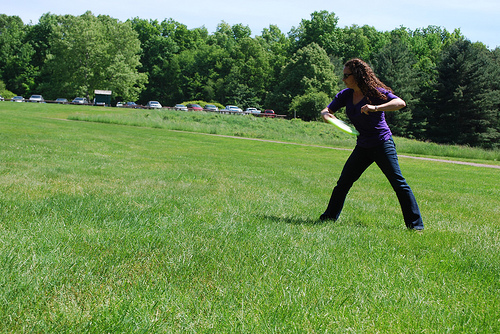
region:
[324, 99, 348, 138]
yellow Frisbee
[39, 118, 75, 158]
short green and yellow grass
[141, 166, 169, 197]
short green and yellow grass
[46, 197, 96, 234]
short green and yellow grass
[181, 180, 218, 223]
short green and yellow grass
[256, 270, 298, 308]
short green and yellow grass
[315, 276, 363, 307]
short green and yellow grass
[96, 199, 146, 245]
short green and yellow grass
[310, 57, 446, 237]
the woman has glasses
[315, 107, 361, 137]
the frisbee is white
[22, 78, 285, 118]
the cars are parked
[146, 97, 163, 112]
the car is white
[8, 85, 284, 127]
the cars are twelve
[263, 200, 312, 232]
shadow is on the ground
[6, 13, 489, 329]
the scene is outdoors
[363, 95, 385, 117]
watch is on the wrist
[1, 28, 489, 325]
the game being played is frisbee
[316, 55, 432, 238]
A woman playing frisbee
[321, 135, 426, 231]
A pair of blue jeans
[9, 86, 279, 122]
Cars parked in a parking lot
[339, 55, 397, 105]
Woman has long brown hair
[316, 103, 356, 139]
Frisbee in a hand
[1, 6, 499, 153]
Many green trees in the background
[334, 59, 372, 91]
Woman is wearing sunglasses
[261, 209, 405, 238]
Shadows on the grass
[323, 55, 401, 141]
A purple colored shirt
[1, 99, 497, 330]
A large grassy field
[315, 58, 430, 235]
Woman preparing to throw frisbee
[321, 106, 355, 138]
White plastic frisbee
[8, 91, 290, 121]
Line of parked cars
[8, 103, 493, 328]
Gras covered park field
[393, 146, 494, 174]
Park dirt trail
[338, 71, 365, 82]
Sunglases on woman's face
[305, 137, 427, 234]
Blue denim pants on woman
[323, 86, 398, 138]
Purple shirt on woman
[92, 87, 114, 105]
Park rest room facilities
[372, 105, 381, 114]
Watch on woman's wrist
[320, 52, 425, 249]
girl standing in a grassy field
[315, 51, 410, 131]
girl playing frisbee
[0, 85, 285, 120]
cars parked near a field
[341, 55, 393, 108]
girl with curly hair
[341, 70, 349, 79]
girl wearing sunglasses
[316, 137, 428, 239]
girl wearing blue jeans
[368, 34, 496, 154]
green pine trees behind a girl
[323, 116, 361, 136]
yellow frisbee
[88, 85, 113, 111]
green shed amidst parked cars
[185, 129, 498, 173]
dirt path through a grassy field